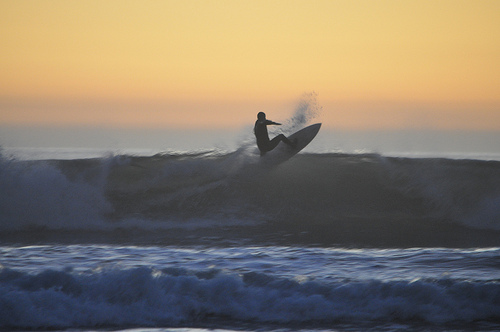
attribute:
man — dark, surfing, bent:
[253, 110, 290, 152]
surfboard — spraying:
[293, 117, 322, 148]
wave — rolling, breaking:
[10, 157, 489, 225]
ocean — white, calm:
[8, 249, 496, 328]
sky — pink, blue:
[13, 5, 499, 20]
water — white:
[287, 100, 322, 124]